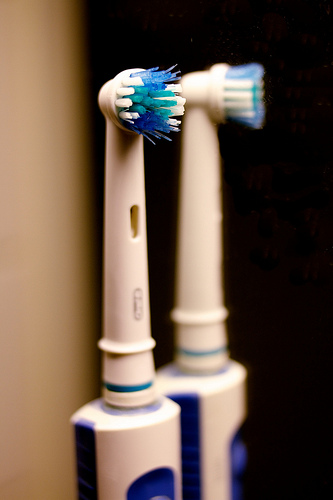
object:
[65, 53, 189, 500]
toothbrush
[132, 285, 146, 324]
logo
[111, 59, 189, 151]
bristles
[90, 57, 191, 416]
brush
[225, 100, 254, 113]
bristle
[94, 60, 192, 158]
head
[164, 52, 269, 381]
brush head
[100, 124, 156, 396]
neck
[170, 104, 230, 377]
handle